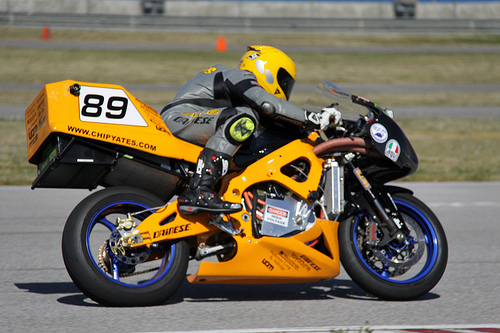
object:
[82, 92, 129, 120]
writing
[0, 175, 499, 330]
highway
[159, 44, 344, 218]
man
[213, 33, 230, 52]
cone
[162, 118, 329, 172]
seat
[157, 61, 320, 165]
outfit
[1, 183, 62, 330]
surface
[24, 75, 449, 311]
bike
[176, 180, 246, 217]
boot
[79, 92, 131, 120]
number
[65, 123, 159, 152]
info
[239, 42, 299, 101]
helmet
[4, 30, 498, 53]
path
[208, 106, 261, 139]
knee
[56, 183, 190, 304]
motorcycle tires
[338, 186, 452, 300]
motorcycle wheel/rims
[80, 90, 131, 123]
racing number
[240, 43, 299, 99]
yellow helmet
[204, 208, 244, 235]
motorcycle's pedal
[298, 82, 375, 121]
glass windshield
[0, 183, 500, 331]
racing track